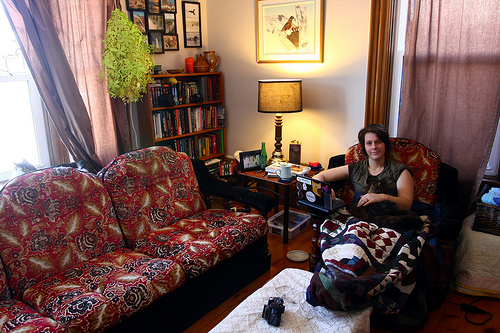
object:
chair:
[309, 139, 458, 271]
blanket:
[307, 193, 441, 310]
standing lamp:
[258, 80, 304, 167]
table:
[238, 162, 318, 243]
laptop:
[296, 175, 348, 212]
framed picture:
[262, 1, 315, 55]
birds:
[280, 16, 294, 32]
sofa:
[0, 146, 268, 330]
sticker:
[306, 192, 315, 203]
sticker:
[312, 181, 322, 197]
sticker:
[296, 183, 303, 198]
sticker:
[296, 177, 311, 185]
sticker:
[302, 184, 307, 190]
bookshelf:
[137, 73, 227, 161]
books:
[187, 107, 192, 132]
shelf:
[156, 128, 225, 142]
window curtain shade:
[387, 0, 500, 175]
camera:
[262, 297, 285, 327]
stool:
[208, 267, 371, 332]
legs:
[328, 212, 372, 306]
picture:
[185, 3, 200, 47]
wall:
[123, 0, 209, 73]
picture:
[163, 35, 177, 49]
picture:
[165, 13, 176, 33]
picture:
[148, 15, 164, 30]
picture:
[151, 32, 163, 52]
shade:
[257, 80, 302, 113]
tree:
[105, 9, 155, 106]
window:
[0, 0, 104, 169]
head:
[12, 158, 37, 173]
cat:
[13, 158, 37, 173]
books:
[210, 79, 212, 100]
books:
[221, 130, 224, 153]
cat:
[349, 179, 423, 232]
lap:
[345, 206, 412, 234]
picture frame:
[239, 149, 262, 172]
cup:
[281, 165, 291, 178]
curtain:
[0, 0, 114, 172]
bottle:
[260, 142, 267, 169]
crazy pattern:
[16, 187, 76, 221]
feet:
[328, 276, 355, 305]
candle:
[185, 57, 194, 73]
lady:
[309, 126, 416, 313]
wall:
[203, 0, 369, 164]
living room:
[0, 0, 500, 332]